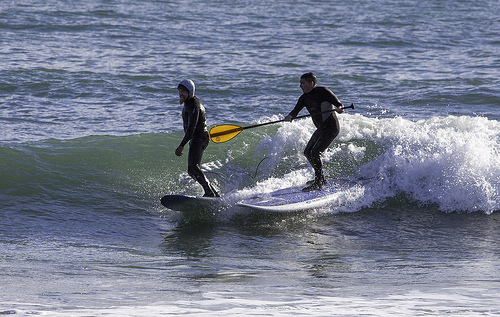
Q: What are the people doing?
A: Surfing.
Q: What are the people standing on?
A: Surfboards.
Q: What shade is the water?
A: Blue.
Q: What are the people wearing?
A: Wet suits.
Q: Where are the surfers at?
A: Beach.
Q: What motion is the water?
A: Wavy.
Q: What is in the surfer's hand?
A: Paddle.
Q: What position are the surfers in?
A: Standing.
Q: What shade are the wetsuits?
A: Black.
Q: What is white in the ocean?
A: Foam.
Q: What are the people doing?
A: Surfing.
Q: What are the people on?
A: Surfboards.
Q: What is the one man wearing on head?
A: Helmet.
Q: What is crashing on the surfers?
A: Wave.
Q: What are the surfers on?
A: Water.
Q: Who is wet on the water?
A: Surfers.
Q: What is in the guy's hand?
A: A paddle.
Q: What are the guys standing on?
A: Surfboards.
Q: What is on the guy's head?
A: Surf cap.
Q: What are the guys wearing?
A: Wet suits.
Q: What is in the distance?
A: Water.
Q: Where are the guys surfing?
A: The ocean.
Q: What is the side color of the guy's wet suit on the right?
A: Gray.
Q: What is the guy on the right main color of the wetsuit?
A: Black.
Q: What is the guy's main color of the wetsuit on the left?
A: Black.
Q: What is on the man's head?
A: A blue helmet.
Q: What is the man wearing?
A: A black water suit.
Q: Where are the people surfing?
A: In the ocean.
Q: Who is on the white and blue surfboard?
A: The man.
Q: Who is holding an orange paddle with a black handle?
A: The surfer.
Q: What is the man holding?
A: Paddle.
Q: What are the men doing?
A: Surfing.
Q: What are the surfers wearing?
A: Wetsuits.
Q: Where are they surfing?
A: Ocean.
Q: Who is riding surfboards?
A: Two men.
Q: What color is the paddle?
A: Gold.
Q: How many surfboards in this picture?
A: Two.